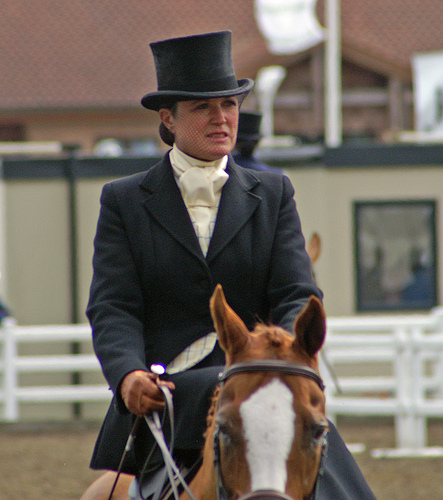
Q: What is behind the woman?
A: A fence.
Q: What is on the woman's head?
A: A top hat.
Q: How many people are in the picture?
A: One.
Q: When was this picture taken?
A: During the day.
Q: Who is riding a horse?
A: The woman.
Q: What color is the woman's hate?
A: Black.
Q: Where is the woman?
A: On a horse.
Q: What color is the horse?
A: Tan.